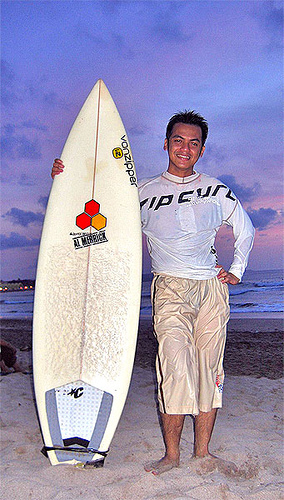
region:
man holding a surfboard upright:
[23, 58, 279, 484]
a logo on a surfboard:
[67, 194, 113, 246]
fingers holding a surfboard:
[41, 156, 73, 179]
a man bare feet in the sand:
[145, 422, 243, 488]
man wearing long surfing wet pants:
[147, 275, 239, 428]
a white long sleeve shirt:
[137, 166, 260, 278]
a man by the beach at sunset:
[132, 80, 274, 475]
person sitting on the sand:
[0, 334, 29, 379]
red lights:
[0, 275, 31, 288]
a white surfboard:
[31, 69, 136, 491]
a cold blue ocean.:
[251, 262, 276, 310]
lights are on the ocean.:
[1, 276, 32, 295]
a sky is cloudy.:
[22, 10, 273, 79]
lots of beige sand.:
[17, 469, 117, 495]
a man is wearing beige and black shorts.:
[147, 317, 240, 388]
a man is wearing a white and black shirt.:
[139, 174, 225, 263]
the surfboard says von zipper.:
[117, 128, 141, 204]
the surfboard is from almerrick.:
[70, 227, 112, 250]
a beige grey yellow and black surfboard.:
[16, 83, 152, 463]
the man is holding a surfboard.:
[30, 66, 277, 481]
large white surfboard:
[39, 73, 123, 464]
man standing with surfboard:
[31, 77, 249, 482]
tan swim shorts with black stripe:
[149, 269, 242, 420]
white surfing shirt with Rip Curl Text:
[145, 168, 255, 279]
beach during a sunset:
[258, 238, 283, 388]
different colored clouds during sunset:
[256, 140, 282, 280]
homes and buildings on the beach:
[1, 274, 32, 316]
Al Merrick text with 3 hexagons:
[69, 199, 116, 262]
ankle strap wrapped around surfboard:
[34, 444, 135, 478]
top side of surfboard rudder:
[45, 366, 118, 462]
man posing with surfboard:
[38, 101, 260, 472]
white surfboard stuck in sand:
[50, 131, 140, 471]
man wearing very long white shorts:
[137, 256, 251, 419]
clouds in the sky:
[5, 124, 45, 237]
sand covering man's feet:
[131, 448, 241, 484]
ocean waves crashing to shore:
[235, 271, 279, 312]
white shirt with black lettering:
[144, 169, 251, 280]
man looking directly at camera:
[143, 108, 223, 188]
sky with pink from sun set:
[237, 181, 281, 267]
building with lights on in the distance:
[1, 275, 37, 296]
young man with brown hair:
[149, 103, 213, 177]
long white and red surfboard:
[24, 73, 143, 452]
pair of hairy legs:
[140, 393, 244, 486]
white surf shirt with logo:
[125, 161, 263, 290]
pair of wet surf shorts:
[136, 265, 239, 426]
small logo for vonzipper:
[106, 125, 148, 193]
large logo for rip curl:
[136, 180, 243, 218]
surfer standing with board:
[6, 77, 264, 466]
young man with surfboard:
[23, 81, 261, 466]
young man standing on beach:
[142, 101, 260, 482]